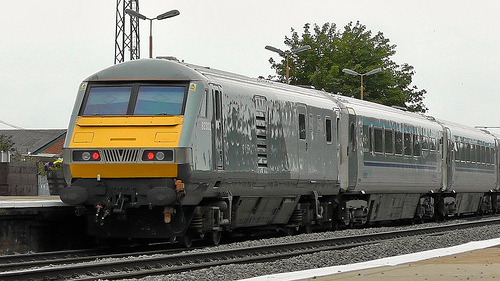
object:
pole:
[146, 18, 154, 63]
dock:
[0, 195, 73, 217]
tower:
[112, 0, 139, 62]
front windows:
[80, 86, 183, 116]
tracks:
[0, 216, 497, 281]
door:
[297, 103, 309, 180]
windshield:
[82, 87, 183, 116]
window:
[365, 125, 496, 164]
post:
[285, 52, 289, 83]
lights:
[342, 67, 382, 76]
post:
[361, 75, 364, 99]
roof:
[0, 128, 67, 155]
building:
[0, 129, 66, 155]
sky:
[0, 0, 500, 72]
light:
[142, 150, 172, 162]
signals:
[72, 148, 172, 162]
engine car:
[58, 56, 500, 248]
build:
[0, 128, 69, 195]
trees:
[256, 20, 428, 111]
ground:
[0, 215, 498, 281]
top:
[79, 54, 336, 104]